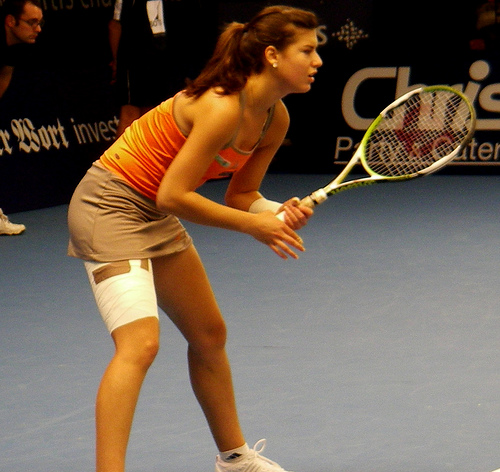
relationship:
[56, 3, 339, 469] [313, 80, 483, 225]
woman holding racket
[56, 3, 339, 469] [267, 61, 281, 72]
woman wears earring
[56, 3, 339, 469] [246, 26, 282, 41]
woman has hair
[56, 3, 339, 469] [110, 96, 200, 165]
woman wears shirt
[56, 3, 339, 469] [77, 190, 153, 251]
woman wears skirt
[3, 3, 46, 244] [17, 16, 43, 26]
man wears glasses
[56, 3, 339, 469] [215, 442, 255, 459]
woman wears sock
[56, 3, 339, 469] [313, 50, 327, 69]
woman has nose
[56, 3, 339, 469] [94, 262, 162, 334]
woman wears wrap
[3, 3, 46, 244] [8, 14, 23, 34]
man has sideburns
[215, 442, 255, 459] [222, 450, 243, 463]
sock has logo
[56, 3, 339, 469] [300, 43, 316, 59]
woman has eye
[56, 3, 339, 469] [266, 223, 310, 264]
woman has fingers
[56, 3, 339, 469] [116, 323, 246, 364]
woman has knees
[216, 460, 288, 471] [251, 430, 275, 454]
shoe has lace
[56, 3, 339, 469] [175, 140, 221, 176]
woman has bicep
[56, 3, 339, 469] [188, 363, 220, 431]
woman has calve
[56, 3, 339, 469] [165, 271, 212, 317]
woman has thigh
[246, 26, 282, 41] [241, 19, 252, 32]
hair in band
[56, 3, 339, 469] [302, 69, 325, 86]
woman has mouth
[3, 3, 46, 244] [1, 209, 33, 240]
man wears shoe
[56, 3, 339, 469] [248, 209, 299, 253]
woman flexes hand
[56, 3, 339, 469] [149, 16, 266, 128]
woman has pony tail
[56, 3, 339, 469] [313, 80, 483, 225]
woman holds racket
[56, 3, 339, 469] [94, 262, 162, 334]
woman has wrap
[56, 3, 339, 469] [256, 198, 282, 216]
woman wears wristband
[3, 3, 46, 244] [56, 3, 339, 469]
man behind woman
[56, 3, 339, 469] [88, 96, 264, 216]
woman wears tank top